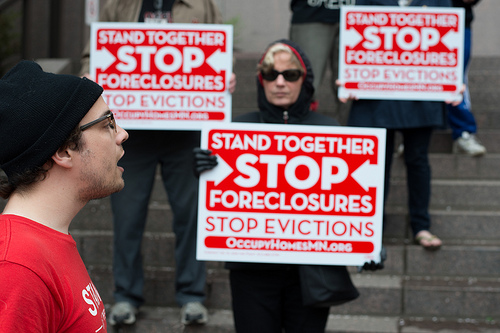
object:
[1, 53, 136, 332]
man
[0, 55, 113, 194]
cap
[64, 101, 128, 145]
glasses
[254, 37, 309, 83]
hair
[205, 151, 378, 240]
protest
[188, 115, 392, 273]
sign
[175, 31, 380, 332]
woman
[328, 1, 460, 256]
woman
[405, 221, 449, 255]
flip flop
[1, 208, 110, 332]
shirt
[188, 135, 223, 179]
glove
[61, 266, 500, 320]
stairs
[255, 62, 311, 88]
sunglasses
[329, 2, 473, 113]
sign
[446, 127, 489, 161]
shoe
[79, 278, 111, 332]
writing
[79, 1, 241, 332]
man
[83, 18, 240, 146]
sign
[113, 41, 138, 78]
letter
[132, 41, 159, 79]
letter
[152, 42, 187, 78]
letter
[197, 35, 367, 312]
jacket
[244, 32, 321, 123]
hood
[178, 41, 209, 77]
letter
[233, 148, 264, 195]
letter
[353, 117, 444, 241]
pants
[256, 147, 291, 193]
letter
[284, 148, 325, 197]
letter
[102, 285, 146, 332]
shoe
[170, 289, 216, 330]
shoe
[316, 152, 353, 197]
letter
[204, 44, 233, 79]
arrow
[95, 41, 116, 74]
arrow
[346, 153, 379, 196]
arrow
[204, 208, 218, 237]
letter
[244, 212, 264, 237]
letter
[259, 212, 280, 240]
letter